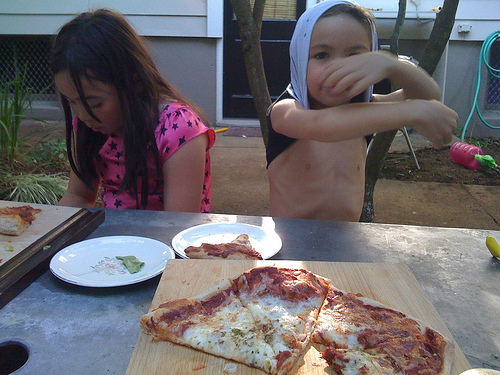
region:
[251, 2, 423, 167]
child has their shirt pulled up over their head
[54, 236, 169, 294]
white plate sitting on the table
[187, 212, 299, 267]
white plate has a slice of pizza on it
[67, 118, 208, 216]
girl is wearing a pink shirt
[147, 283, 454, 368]
pizza is laying on the cutting board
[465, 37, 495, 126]
hose hanging on the side of the house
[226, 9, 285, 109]
tree behind the child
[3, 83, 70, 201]
bush behind the girl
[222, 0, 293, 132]
black door on the house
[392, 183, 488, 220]
cement walk behind the kids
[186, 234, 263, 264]
pizza on a plate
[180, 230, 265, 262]
pizza on a white plate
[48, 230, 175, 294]
white plate on the table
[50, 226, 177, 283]
plate on the table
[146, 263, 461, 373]
pizza on the wooden slab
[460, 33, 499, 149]
hose next to house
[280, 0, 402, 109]
boy has shirt on his head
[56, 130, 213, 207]
pink shirt on girl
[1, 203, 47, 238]
pizza on the wooden block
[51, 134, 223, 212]
shirt on the girl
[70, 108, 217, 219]
a pink shirt with black stars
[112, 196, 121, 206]
a black star on a shirt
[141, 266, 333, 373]
two slices of cheese pizza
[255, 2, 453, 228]
a little boy with his shirt over his head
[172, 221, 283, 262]
a white plate with pizza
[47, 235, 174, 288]
an empty white plate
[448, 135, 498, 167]
a pink and green plastic toy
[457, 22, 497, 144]
a wound green hose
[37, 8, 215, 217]
long dark hair on a little girl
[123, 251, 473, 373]
a tan wooden cutting board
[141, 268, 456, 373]
Pizza on the board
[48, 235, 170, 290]
A white plate on the table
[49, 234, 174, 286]
The white plate is circular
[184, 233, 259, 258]
A slice of pizza on the plate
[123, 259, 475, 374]
A wooden board beneath the pizza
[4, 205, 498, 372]
A table beneath the food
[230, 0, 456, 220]
A tree behind the children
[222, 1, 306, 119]
A door behind the tree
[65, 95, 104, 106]
The eyes of the girl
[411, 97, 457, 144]
The right hand of the child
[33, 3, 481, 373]
Two children sitting at the table eating pizza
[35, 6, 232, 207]
young girl sitting at the table looking down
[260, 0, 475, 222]
young child being funny at the table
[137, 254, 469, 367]
fresh pizza sitting on a wooden board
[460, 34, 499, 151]
green garden hose hanging on the side of the house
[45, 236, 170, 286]
small white circular plate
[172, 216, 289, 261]
small white circular plate with a slice of pizza on it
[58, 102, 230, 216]
short sleeved pink shirt with black stars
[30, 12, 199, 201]
girl with long brunette hair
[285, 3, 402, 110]
boy with shirt on his head